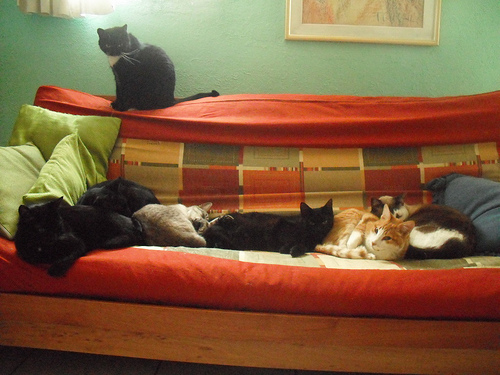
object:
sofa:
[0, 84, 500, 375]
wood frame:
[0, 293, 500, 375]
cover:
[32, 84, 499, 149]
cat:
[314, 201, 415, 260]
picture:
[282, 0, 441, 47]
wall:
[0, 0, 500, 148]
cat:
[96, 23, 221, 112]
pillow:
[0, 139, 47, 243]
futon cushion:
[0, 235, 500, 325]